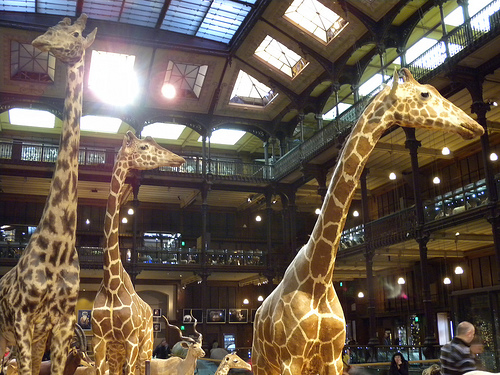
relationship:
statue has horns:
[12, 13, 75, 375] [54, 16, 94, 30]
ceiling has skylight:
[12, 1, 319, 138] [90, 48, 150, 109]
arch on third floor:
[202, 120, 285, 186] [0, 102, 298, 183]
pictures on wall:
[166, 301, 261, 325] [130, 269, 304, 348]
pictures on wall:
[204, 310, 227, 326] [130, 269, 304, 348]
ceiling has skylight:
[12, 1, 319, 138] [82, 48, 145, 108]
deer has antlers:
[146, 336, 211, 372] [154, 310, 208, 346]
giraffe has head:
[265, 11, 470, 375] [376, 74, 483, 149]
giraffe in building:
[265, 11, 470, 375] [3, 6, 499, 367]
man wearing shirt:
[442, 307, 481, 374] [429, 335, 474, 372]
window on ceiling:
[212, 71, 269, 121] [12, 1, 319, 138]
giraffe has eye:
[265, 11, 470, 375] [411, 85, 439, 103]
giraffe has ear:
[265, 11, 470, 375] [388, 57, 414, 83]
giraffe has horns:
[265, 11, 470, 375] [54, 16, 94, 30]